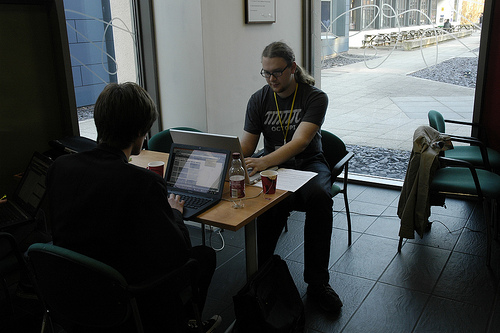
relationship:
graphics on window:
[316, 3, 483, 80] [293, 2, 482, 187]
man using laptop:
[41, 81, 220, 332] [154, 122, 281, 222]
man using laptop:
[240, 41, 344, 312] [157, 110, 293, 184]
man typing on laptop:
[41, 81, 220, 332] [151, 140, 241, 222]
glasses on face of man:
[259, 65, 290, 78] [231, 40, 350, 310]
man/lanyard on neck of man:
[240, 41, 329, 169] [213, 31, 363, 327]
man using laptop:
[240, 41, 344, 312] [165, 122, 280, 186]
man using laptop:
[231, 40, 350, 310] [169, 117, 267, 177]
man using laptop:
[41, 81, 220, 332] [157, 138, 225, 225]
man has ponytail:
[240, 41, 344, 312] [292, 62, 317, 89]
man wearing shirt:
[231, 40, 350, 310] [242, 80, 330, 170]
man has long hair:
[240, 41, 344, 312] [260, 41, 315, 81]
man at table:
[240, 41, 344, 312] [130, 131, 317, 237]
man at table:
[231, 40, 350, 310] [58, 135, 315, 310]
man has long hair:
[39, 80, 221, 332] [263, 40, 319, 86]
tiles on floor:
[359, 241, 499, 331] [279, 177, 499, 331]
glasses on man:
[246, 57, 291, 81] [240, 41, 344, 312]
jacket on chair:
[396, 124, 455, 240] [397, 124, 491, 253]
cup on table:
[259, 168, 277, 191] [124, 144, 318, 298]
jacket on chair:
[396, 124, 460, 238] [397, 124, 491, 253]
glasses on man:
[259, 65, 290, 78] [240, 41, 344, 312]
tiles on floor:
[341, 183, 499, 331] [204, 179, 493, 331]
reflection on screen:
[176, 150, 218, 195] [166, 144, 226, 196]